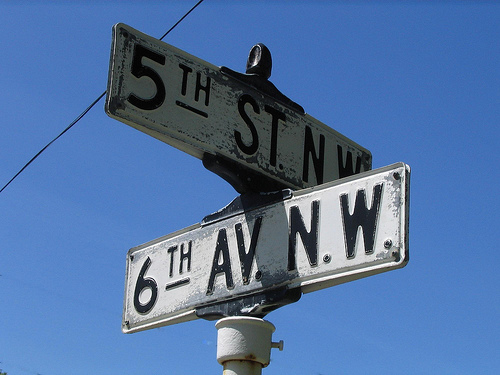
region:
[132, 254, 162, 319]
The number is black.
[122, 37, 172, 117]
The numbr is black.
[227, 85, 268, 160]
The letter is black.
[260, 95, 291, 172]
The letter is black.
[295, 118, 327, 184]
The letter is black.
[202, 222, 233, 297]
The letter is black.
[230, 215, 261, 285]
The letter is black.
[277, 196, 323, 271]
The letter is black.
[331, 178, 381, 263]
The letter is black.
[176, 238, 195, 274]
The letter is black.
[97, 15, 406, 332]
two black and white street signs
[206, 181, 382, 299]
black lettering on white background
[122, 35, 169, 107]
black number on white background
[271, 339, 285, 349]
white screw on white pole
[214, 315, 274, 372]
white pole holding up signs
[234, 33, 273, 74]
black screw on top of sign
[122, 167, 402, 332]
bolts holding the sign to the pole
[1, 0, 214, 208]
black power line above sign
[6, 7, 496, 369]
blue sky behind two signs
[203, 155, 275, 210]
brackets attaching sign to each other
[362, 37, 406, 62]
white clouds in blue sky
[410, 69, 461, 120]
white clouds in blue sky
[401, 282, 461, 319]
white clouds in blue sky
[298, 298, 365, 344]
white clouds in blue sky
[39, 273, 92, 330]
white clouds in blue sky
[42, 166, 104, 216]
white clouds in blue sky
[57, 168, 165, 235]
white clouds in blue sky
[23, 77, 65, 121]
white clouds in blue sky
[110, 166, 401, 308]
black and white sign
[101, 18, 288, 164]
black and white sign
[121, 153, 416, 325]
the street sign says 6th av. n.w.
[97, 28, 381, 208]
the street sign says 5th st n.w.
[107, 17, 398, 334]
the cross streets are 5th st and 6th av.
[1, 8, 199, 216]
wire above the street sign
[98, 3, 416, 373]
a street sign with black lettering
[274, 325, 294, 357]
nail on the street sign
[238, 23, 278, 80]
top cap on the street sign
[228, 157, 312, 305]
shadow casted from the sign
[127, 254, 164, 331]
the number 6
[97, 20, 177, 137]
the number 5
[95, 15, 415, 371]
two signs on a pole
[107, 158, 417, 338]
a sign is color gray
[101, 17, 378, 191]
a sign is color gray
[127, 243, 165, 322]
number 6 on sign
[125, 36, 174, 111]
number 5 on sign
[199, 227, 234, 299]
letter A on sign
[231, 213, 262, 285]
letter V on sign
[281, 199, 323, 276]
letter N on sign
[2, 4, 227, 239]
a black wire over signs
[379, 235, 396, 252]
a dot on a sig